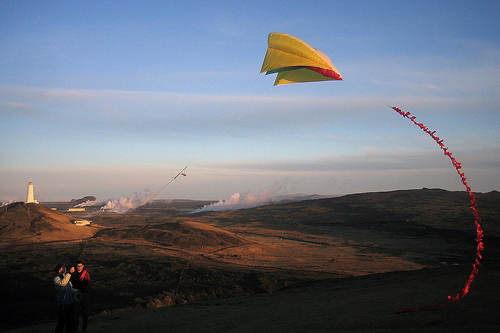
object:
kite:
[258, 31, 488, 315]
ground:
[434, 193, 476, 241]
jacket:
[70, 270, 91, 290]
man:
[68, 262, 94, 296]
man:
[51, 264, 77, 315]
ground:
[328, 192, 360, 241]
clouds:
[0, 0, 499, 201]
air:
[0, 1, 499, 120]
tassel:
[342, 106, 488, 312]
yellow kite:
[259, 31, 344, 87]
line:
[112, 86, 275, 233]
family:
[48, 257, 95, 323]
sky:
[1, 0, 498, 201]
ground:
[270, 237, 370, 276]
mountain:
[201, 187, 498, 274]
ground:
[105, 310, 219, 331]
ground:
[41, 192, 145, 296]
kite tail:
[385, 107, 485, 316]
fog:
[97, 193, 153, 215]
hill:
[0, 199, 108, 246]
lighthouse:
[26, 179, 39, 205]